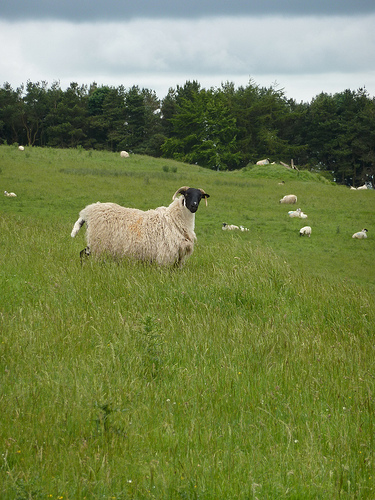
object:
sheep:
[68, 186, 211, 271]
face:
[179, 188, 204, 214]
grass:
[51, 195, 154, 323]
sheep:
[278, 191, 298, 205]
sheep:
[296, 224, 312, 239]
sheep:
[350, 225, 371, 241]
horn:
[171, 184, 185, 202]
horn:
[199, 187, 209, 210]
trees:
[11, 81, 62, 149]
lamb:
[2, 189, 17, 198]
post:
[289, 156, 294, 172]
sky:
[0, 0, 375, 120]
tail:
[69, 215, 86, 239]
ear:
[177, 188, 188, 196]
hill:
[0, 141, 372, 497]